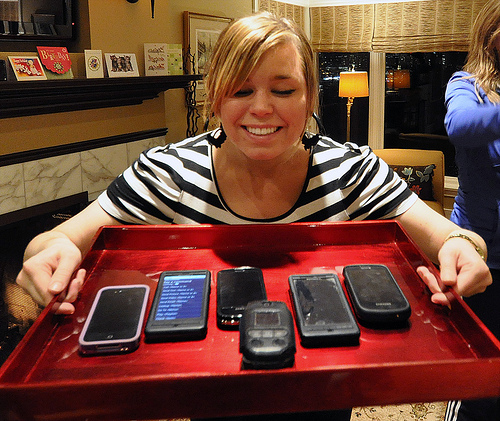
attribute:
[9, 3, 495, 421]
woman — smiling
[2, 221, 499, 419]
tray — red, black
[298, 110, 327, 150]
earring — black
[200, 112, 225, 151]
earring — black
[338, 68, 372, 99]
shade — yellow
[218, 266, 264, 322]
phone — black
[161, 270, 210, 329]
display — blue, white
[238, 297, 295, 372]
phone — closed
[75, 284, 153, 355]
phone — white rimmed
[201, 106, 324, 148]
earrings — black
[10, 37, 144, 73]
animals — present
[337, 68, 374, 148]
lamp — present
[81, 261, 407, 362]
cell phones — six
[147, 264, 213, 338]
phone — on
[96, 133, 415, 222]
shirt — black, white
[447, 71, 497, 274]
shirt — blue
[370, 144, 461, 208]
chair — brown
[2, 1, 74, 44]
mirror — present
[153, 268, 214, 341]
phone — present, rectangular, lit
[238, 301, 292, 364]
phone — flip phone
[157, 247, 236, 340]
iphone — existing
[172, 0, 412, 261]
lady — young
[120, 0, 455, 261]
lady — young